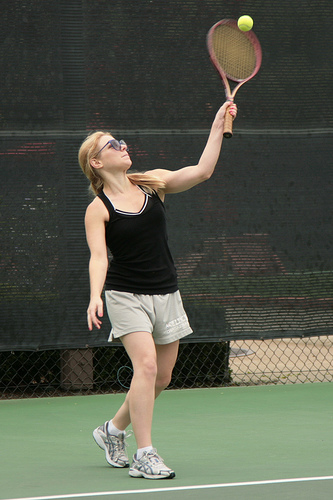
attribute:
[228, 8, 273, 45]
tennis ball — green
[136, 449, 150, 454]
sock — white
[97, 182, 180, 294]
top — black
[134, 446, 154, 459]
sock — white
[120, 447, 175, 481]
shoe — white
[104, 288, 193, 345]
shorts — white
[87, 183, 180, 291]
top — black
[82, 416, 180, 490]
shoes — white, gray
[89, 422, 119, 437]
heel — lifted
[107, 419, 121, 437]
sock — white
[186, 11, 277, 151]
tennis racket — red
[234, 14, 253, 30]
ball — yellow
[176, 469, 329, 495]
line — white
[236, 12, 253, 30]
ball — bright, yellow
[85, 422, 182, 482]
shoes — white and grey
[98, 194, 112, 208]
strap — thick, black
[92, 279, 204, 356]
shorts — grey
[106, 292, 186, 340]
shorts — grey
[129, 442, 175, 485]
tennis shoe — white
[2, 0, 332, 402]
fence — tall, wire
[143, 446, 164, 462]
shoe lace — white